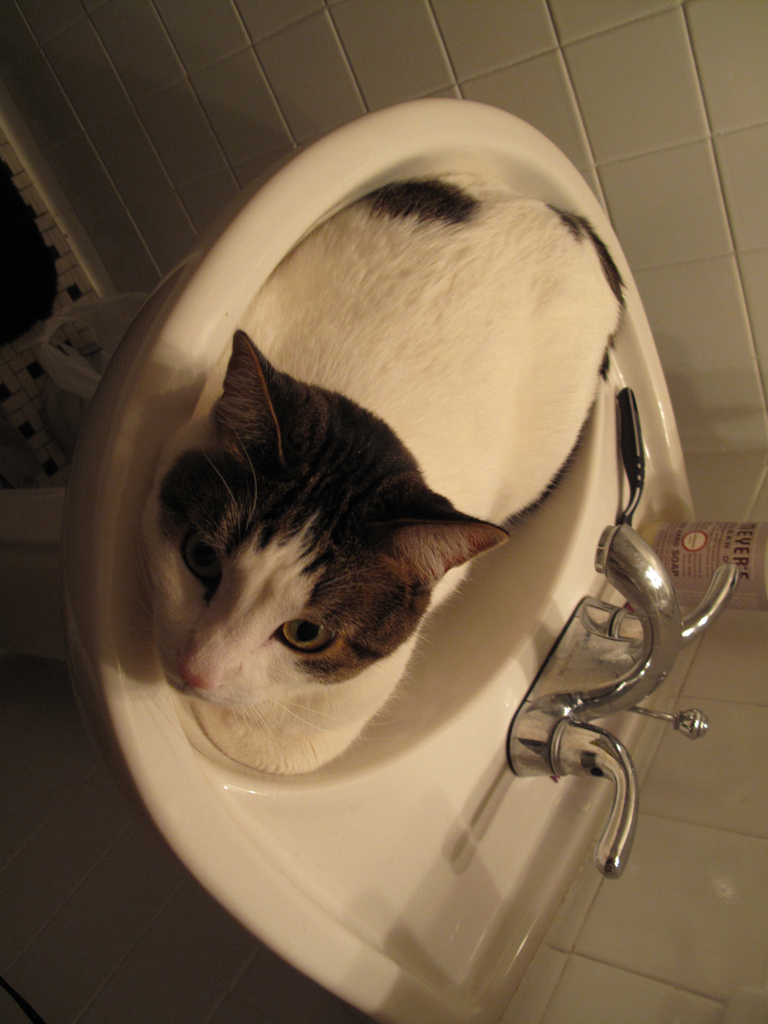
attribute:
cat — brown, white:
[94, 194, 670, 827]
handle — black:
[609, 381, 688, 519]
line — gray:
[624, 395, 650, 470]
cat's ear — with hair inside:
[375, 508, 511, 591]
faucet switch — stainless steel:
[553, 710, 640, 883]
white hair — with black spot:
[335, 173, 515, 389]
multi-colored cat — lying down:
[137, 167, 631, 784]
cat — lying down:
[135, 166, 625, 780]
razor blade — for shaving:
[613, 379, 649, 538]